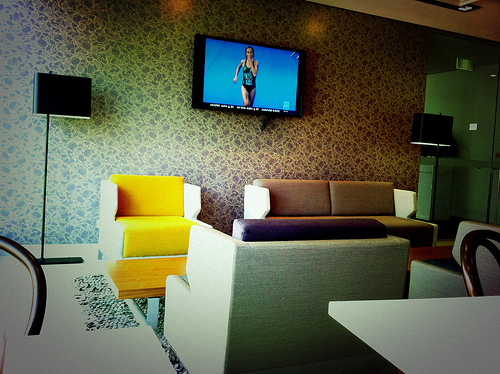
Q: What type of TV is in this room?
A: Flat screen.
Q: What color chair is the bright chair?
A: Yellow.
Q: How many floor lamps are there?
A: 2.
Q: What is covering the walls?
A: Patterned wallpaper.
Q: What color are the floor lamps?
A: Black.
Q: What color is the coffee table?
A: Light brown.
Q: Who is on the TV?
A: A woman running.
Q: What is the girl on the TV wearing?
A: Bathing suit.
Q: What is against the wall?
A: A chair.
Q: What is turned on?
A: The television.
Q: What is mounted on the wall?
A: The television.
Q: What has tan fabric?
A: Loveseat.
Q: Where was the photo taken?
A: In a room.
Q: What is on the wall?
A: Wallpaper.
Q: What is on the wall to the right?
A: Cabinets.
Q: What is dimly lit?
A: The room.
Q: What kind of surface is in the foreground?
A: White.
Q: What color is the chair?
A: Yellow and white.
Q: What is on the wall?
A: Tv.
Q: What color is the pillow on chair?
A: Gray and purple.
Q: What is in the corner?
A: Green boxes.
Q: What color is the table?
A: Gray.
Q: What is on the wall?
A: Spots.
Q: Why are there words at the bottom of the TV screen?
A: So deaf persons can read.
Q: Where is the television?
A: On the wall.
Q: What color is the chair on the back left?
A: Yellow.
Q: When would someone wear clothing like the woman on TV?
A: To swim.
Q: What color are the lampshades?
A: Black.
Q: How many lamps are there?
A: 2.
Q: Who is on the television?
A: A woman.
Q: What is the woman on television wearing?
A: Swimsuit.